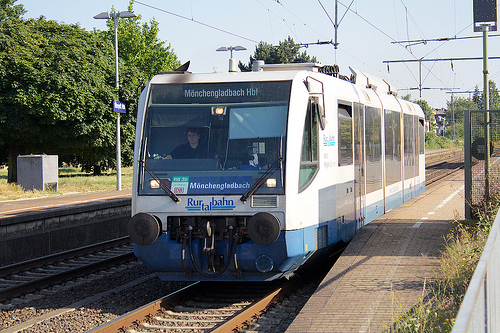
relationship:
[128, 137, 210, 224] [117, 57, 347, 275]
wiper on train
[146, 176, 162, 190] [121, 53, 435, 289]
headlight on train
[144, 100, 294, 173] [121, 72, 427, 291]
window on train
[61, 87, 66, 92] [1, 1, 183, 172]
leaves on trees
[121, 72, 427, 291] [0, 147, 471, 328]
train on train tracks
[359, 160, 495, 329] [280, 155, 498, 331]
line on ground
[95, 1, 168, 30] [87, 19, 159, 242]
lamps on pole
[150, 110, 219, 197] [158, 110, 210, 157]
man wearing shirt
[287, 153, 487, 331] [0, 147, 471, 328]
walkway next to train tracks